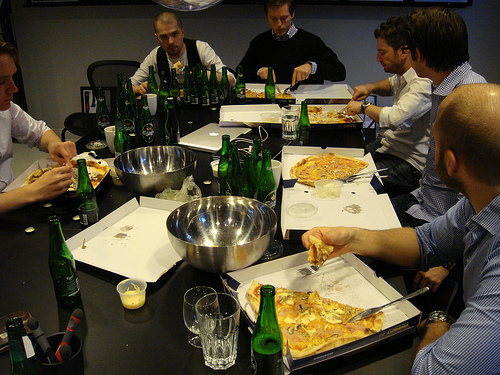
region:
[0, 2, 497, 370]
group of men eating pizza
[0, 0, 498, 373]
a pizza dinner party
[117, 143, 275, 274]
large silver bowls on table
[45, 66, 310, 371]
green bear bottles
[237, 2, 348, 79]
guy in black sweater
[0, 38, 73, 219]
only guy on the left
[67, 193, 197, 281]
empty pizza box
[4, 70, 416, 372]
black table covered in pizza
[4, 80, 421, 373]
table with pizza and bear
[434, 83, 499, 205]
back of man's head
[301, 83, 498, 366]
this is a person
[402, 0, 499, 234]
this is a person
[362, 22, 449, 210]
this is a person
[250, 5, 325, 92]
this is a person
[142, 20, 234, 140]
this is a person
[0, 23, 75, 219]
this is a person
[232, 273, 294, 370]
a bottle of soda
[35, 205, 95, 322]
a bottle of soda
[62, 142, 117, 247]
a bottle of soda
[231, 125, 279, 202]
a bottle of soda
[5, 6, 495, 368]
men sitting around black table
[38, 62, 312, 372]
green glass bottles littering the table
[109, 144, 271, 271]
two silver bowls on table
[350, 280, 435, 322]
knife stuck in pizza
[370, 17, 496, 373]
two men in blue shirts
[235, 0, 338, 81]
man in black sweater cutting pizza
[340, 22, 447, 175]
man in white collared shirt eating pizza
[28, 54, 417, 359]
six boxes of pizza on black table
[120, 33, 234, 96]
man wearing black vest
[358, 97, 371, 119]
black and silver watch on man's wrist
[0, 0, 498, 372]
Men sitting around a table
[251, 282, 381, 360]
Piece of pizza in a box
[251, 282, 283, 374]
Green glass of drink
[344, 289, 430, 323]
Silver knife on pizza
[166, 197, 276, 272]
Silver bowl on table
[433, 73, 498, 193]
Man with a balded head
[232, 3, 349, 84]
Man wearing a black sweater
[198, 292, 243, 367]
Colorless glass on table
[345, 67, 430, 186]
Man wearing white shirt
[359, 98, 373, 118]
Black and white wrist watch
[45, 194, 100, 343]
This is a bottle of beer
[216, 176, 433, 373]
This is a pizza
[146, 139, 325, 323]
This is a large bowl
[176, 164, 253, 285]
The bowl is silver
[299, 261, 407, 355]
This is a cardboard box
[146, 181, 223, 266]
The bowl is metal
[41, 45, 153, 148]
This is a chair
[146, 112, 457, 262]
These are men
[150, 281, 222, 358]
These are glasses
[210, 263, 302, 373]
The bottles are green